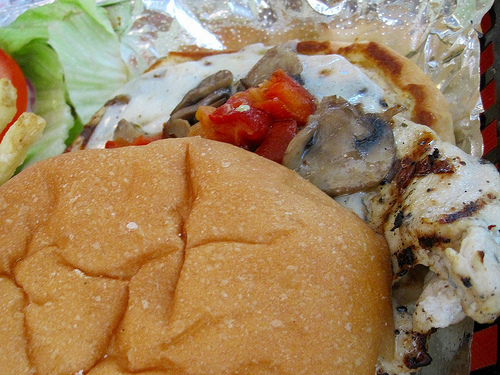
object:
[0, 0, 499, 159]
aluminum foil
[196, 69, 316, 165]
pepper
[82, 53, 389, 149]
cheese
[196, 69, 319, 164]
tomato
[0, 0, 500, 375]
plate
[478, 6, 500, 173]
basket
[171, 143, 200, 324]
crease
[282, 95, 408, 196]
mushroom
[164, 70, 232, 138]
mushroom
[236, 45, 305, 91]
mushroom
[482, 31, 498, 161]
rack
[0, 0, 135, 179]
lettuce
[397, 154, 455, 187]
burnt bit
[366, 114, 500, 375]
grilled chicken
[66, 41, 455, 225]
frisbee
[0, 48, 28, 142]
tomato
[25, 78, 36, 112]
onion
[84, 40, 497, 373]
egg white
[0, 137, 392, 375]
bun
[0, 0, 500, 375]
sandwich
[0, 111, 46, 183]
french fry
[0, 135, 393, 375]
pizza